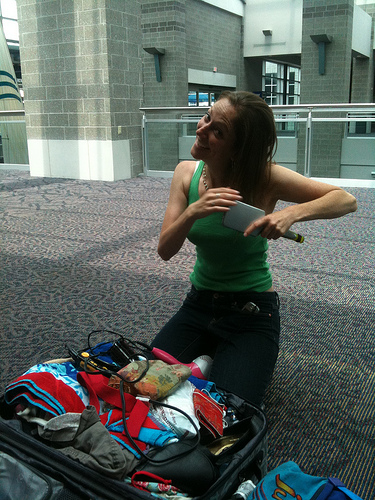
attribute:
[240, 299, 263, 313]
cell phone — silver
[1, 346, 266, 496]
suitcase — open, black, full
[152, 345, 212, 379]
hair dryer — pink, silver, gray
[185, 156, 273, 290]
tank top — green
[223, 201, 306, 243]
brush — gray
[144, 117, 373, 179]
guard — glass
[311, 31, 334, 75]
fixture — black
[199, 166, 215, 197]
necklace — gold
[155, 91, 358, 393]
woman — skinny, smiling, combing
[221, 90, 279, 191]
hair — brown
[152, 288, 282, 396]
jeans — blue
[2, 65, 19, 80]
pattern — dark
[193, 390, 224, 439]
wallet — red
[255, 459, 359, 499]
pack — blue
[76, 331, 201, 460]
wire — black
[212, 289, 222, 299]
button — silver